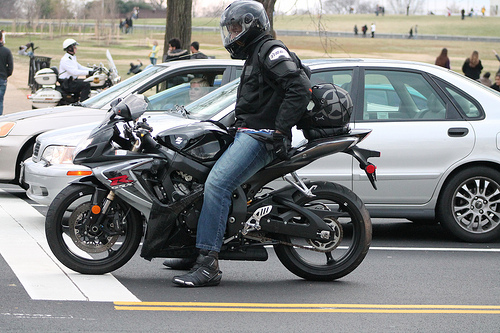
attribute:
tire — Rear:
[267, 178, 381, 285]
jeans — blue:
[208, 120, 270, 259]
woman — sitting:
[172, 54, 216, 99]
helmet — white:
[58, 32, 79, 51]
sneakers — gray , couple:
[177, 250, 221, 290]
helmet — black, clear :
[219, 1, 275, 58]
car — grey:
[23, 59, 497, 241]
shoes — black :
[167, 254, 225, 285]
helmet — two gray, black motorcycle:
[218, 1, 273, 62]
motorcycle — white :
[23, 33, 108, 109]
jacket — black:
[233, 36, 314, 131]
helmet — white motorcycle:
[205, 6, 323, 70]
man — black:
[159, 7, 310, 290]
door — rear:
[350, 67, 485, 220]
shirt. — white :
[56, 55, 90, 81]